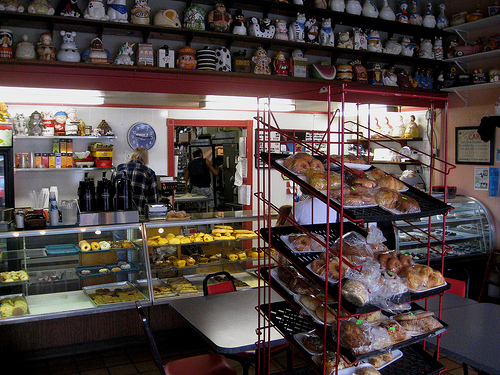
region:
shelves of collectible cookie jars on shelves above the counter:
[0, 3, 498, 86]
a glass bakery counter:
[4, 213, 262, 326]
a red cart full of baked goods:
[266, 85, 461, 374]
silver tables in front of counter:
[169, 281, 499, 373]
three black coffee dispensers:
[76, 167, 132, 213]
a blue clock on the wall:
[127, 125, 157, 150]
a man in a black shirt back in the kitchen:
[186, 150, 221, 205]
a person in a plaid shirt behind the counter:
[112, 145, 159, 204]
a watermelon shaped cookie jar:
[311, 60, 336, 79]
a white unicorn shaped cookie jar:
[116, 42, 136, 64]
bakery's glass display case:
[6, 190, 492, 320]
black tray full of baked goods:
[262, 151, 452, 222]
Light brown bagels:
[78, 238, 90, 251]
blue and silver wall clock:
[126, 121, 157, 150]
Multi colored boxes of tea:
[32, 139, 72, 166]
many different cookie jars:
[2, 3, 498, 91]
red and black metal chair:
[133, 298, 237, 372]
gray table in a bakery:
[169, 285, 312, 355]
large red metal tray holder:
[256, 88, 460, 367]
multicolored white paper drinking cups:
[48, 193, 59, 223]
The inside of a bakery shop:
[20, 11, 485, 374]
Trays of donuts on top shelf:
[294, 152, 395, 214]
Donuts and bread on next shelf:
[301, 236, 431, 295]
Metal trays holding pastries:
[278, 171, 445, 237]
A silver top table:
[166, 291, 242, 374]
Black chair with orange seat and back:
[133, 303, 207, 374]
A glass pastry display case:
[4, 228, 260, 323]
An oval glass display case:
[419, 182, 498, 252]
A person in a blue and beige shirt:
[117, 146, 174, 219]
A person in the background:
[179, 132, 221, 204]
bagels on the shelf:
[285, 152, 324, 174]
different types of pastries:
[280, 151, 444, 373]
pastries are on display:
[0, 225, 257, 321]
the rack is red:
[254, 88, 466, 374]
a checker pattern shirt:
[116, 160, 157, 203]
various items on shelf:
[2, 1, 497, 91]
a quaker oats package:
[1, 29, 12, 56]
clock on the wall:
[128, 121, 155, 150]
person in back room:
[184, 146, 218, 211]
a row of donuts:
[77, 238, 131, 250]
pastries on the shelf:
[289, 144, 433, 373]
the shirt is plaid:
[115, 160, 159, 213]